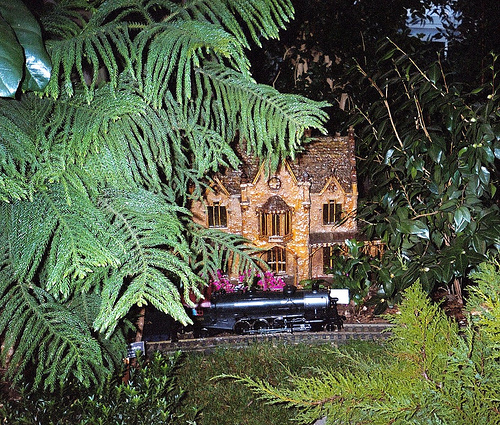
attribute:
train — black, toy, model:
[166, 279, 343, 341]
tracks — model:
[121, 322, 391, 354]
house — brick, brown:
[170, 133, 392, 289]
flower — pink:
[275, 279, 285, 292]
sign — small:
[123, 341, 147, 360]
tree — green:
[3, 3, 332, 391]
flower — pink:
[221, 282, 236, 293]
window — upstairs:
[257, 197, 296, 244]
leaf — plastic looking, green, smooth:
[451, 207, 465, 228]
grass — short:
[161, 340, 391, 422]